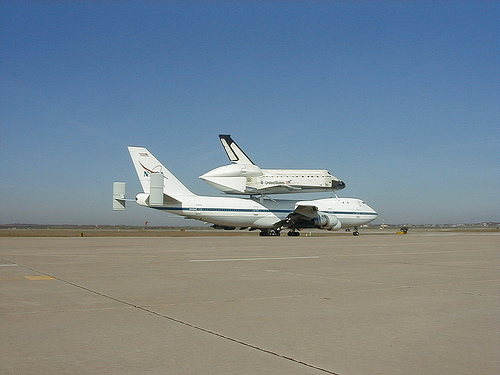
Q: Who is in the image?
A: Planes.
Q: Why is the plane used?
A: To travel.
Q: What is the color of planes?
A: White.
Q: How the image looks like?
A: Interesting.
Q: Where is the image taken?
A: Runway.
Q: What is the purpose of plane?
A: Travel.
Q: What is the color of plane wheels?
A: Black.